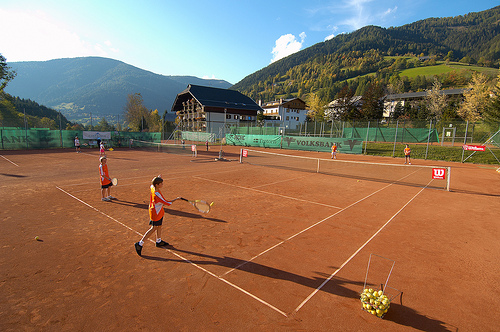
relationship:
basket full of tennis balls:
[362, 252, 406, 314] [360, 291, 389, 316]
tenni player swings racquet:
[135, 177, 183, 254] [183, 196, 211, 215]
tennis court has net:
[2, 138, 500, 331] [241, 147, 451, 188]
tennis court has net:
[2, 138, 500, 331] [130, 139, 198, 158]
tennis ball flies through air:
[210, 201, 215, 205] [0, 2, 500, 332]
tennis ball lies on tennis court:
[36, 235, 41, 242] [2, 138, 500, 331]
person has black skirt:
[98, 155, 113, 203] [101, 181, 114, 188]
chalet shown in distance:
[177, 82, 260, 135] [7, 51, 500, 155]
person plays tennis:
[98, 155, 113, 203] [3, 120, 499, 330]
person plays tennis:
[135, 177, 183, 254] [3, 120, 499, 330]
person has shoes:
[135, 177, 183, 254] [133, 238, 170, 255]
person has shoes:
[98, 155, 113, 203] [103, 200, 116, 204]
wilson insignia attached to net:
[432, 169, 447, 180] [241, 147, 451, 188]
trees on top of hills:
[0, 2, 500, 129] [3, 3, 500, 130]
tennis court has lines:
[2, 138, 500, 331] [3, 154, 444, 317]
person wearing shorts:
[135, 177, 183, 254] [148, 217, 164, 229]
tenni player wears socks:
[135, 177, 183, 254] [137, 238, 163, 246]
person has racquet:
[98, 155, 113, 203] [104, 173, 120, 186]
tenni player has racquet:
[135, 177, 183, 254] [183, 196, 211, 215]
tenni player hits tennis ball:
[135, 177, 183, 254] [210, 201, 215, 205]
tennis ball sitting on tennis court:
[36, 235, 41, 242] [2, 138, 500, 331]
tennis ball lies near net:
[247, 165, 248, 169] [241, 147, 451, 188]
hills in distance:
[3, 3, 500, 130] [7, 51, 500, 155]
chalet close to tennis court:
[177, 82, 260, 135] [2, 138, 500, 331]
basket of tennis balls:
[362, 252, 406, 314] [360, 291, 389, 316]